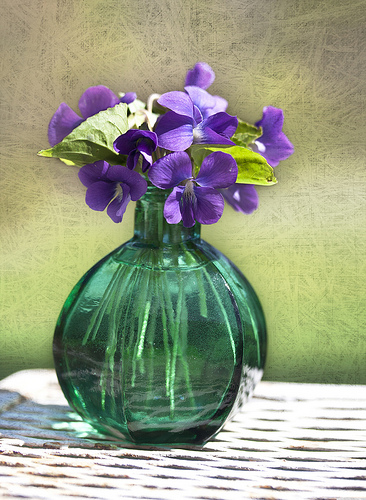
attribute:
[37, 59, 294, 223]
flower — purple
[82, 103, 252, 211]
flower — purple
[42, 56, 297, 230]
flowers — Purple 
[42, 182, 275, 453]
vase — green, purple, glass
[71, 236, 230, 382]
stems — green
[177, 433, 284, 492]
grate — white 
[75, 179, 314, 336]
vase — green 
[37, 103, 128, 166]
leaf — green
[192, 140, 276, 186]
leaf — green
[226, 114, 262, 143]
leaf — green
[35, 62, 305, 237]
bouquet — small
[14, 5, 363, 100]
background — patterned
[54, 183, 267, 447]
vase — glass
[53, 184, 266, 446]
glass — green , blue 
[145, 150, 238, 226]
flower — purple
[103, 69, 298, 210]
flower — purple 